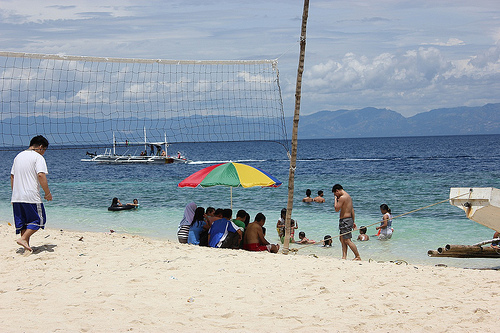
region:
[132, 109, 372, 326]
people sitting under the umbrella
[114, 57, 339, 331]
a people sitting on the sand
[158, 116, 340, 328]
people sittin gon the beach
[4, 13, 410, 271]
a beach volly ball net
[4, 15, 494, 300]
a volley ball net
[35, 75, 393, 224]
a boat in the water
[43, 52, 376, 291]
a boat parked on the water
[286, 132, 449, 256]
people in the water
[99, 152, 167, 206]
people on tubes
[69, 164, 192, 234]
people on tubes in the water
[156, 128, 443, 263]
People are on a beach.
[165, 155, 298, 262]
People sit under an umbrella.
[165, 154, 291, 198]
The umbrella is multicolored.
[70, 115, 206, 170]
A boat is on the water.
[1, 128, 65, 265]
A man walks on the sand.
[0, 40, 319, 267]
A volleyball net is on the beach.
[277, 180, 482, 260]
A boat is tied with a rope.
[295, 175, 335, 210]
The people are in the water.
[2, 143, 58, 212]
The man wears a white top.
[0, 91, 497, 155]
Mountains are in the background.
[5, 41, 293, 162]
an extended volleyball net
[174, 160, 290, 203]
a rainbow colored beach umbrella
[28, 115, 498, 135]
a long mountain range by the ocean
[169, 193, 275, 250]
a group of people huddled under an umbrella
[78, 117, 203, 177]
a recreational ocean vehicle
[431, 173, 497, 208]
the front end of a white boat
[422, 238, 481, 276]
three metal pipes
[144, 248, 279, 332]
clean white sand on a beach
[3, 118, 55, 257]
a man in a white shirt and blue and white shorts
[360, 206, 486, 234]
a rope anchoring a boat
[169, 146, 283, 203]
a brightly colored beach umbrella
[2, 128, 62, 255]
man in white t-shirt and blue swim trunks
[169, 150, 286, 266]
group of people under the umbrella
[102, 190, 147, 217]
two people with a black tube float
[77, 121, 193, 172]
a white boat in the ocean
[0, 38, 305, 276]
volleyball net on the beach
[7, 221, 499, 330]
white sandy beach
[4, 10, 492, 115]
puffy white clouds in the sky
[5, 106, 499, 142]
mountains in the distance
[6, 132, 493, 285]
people enjoying a day at the beach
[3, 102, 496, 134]
A mountain range in the background.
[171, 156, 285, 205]
A multi-colored umbrella.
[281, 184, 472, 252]
A rope attached to a boat.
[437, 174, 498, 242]
A white part of a boat.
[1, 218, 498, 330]
Beige colored sand.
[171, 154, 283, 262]
People sitting under an umbrella.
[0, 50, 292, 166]
A volleyball net.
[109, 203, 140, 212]
A black tube.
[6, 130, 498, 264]
The ocean.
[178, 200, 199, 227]
A white towel.